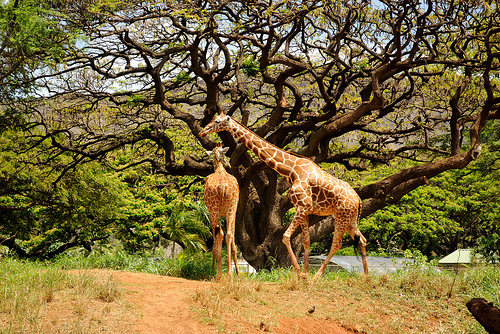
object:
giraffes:
[202, 109, 356, 308]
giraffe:
[201, 149, 250, 272]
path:
[79, 256, 268, 332]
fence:
[245, 240, 490, 275]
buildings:
[441, 240, 499, 270]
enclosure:
[22, 48, 485, 315]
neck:
[226, 122, 291, 172]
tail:
[209, 185, 229, 237]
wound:
[435, 137, 487, 192]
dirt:
[141, 282, 287, 331]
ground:
[32, 267, 430, 334]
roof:
[440, 242, 477, 265]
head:
[209, 134, 228, 170]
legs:
[288, 190, 356, 271]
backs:
[308, 151, 371, 217]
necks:
[216, 118, 250, 177]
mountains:
[138, 79, 432, 135]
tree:
[30, 145, 210, 265]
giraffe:
[200, 67, 380, 280]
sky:
[85, 22, 235, 79]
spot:
[240, 312, 274, 333]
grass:
[148, 242, 211, 277]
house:
[320, 254, 430, 280]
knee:
[273, 217, 305, 252]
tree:
[48, 12, 483, 267]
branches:
[115, 7, 469, 99]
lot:
[67, 14, 483, 110]